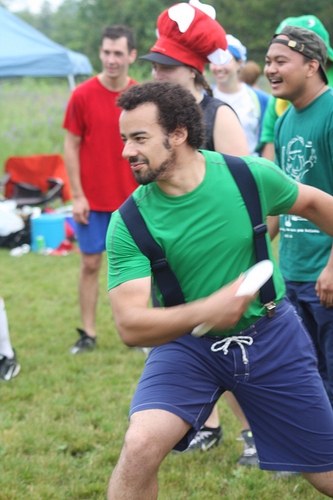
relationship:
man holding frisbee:
[85, 34, 278, 380] [238, 238, 312, 333]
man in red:
[85, 35, 150, 231] [71, 96, 158, 183]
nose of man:
[118, 129, 163, 174] [85, 34, 278, 380]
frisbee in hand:
[238, 238, 312, 333] [190, 270, 262, 342]